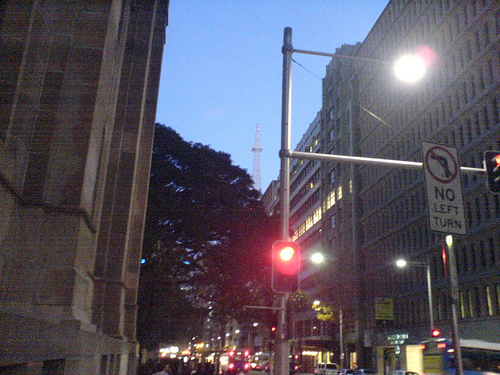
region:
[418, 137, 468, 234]
no left turn sign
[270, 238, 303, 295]
red traffic signal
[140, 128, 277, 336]
green leaves on tree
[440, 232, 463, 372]
silver iron sign post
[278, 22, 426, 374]
lit street light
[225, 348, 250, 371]
brake lights on back of bus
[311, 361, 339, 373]
white van parked on side of road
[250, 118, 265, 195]
tall metal tower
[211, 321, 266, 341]
row of lit street lights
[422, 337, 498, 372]
blue and white us driving on street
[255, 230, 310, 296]
red traffic light on pole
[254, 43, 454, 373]
pole is light grey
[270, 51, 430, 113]
white light on pole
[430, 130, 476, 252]
red and black sign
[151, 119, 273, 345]
tall and green tree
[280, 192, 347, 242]
lights on in building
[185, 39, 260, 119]
blue and clear sky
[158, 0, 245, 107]
no clouds in sky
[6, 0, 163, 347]
tall and brown building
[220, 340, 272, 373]
red lights on cars on street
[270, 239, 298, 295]
a stoplight showing red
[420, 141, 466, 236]
sign for no left turns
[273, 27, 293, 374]
a tall metal post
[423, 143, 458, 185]
red circle around black arrow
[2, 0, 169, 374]
a large stone building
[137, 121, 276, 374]
a large tree is in bloom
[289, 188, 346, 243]
windows letting out light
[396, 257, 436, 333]
a street light is illuminated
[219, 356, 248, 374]
back of a car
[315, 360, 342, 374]
a car is parked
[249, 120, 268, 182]
top of pointed structure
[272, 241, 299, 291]
glowing red on traffic light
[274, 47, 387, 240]
horizontal pole on vertical pole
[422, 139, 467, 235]
sign with red circle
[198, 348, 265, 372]
traffic on city street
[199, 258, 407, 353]
line of lights over street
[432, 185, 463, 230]
three black words on sign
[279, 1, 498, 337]
face of city buildings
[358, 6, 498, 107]
a light on the outside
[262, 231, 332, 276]
a red light on the outside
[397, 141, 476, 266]
a sign on the outside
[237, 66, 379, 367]
a pole on the outside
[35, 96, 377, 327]
a building near a light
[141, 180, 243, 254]
a tree with green leaves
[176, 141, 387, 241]
a tree near a building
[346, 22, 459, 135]
a light on a pole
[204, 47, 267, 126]
a clear blue sky